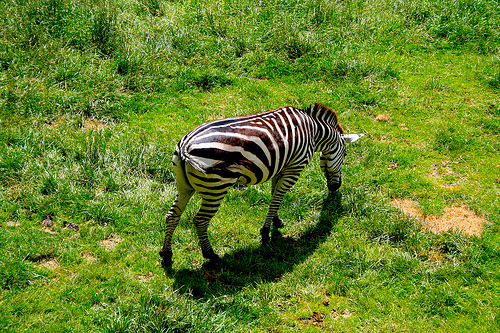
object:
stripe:
[180, 134, 272, 166]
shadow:
[168, 189, 344, 305]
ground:
[0, 1, 499, 332]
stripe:
[187, 147, 262, 187]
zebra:
[155, 100, 366, 275]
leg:
[191, 187, 223, 258]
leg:
[256, 171, 304, 232]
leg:
[158, 186, 192, 255]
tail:
[173, 144, 256, 183]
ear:
[340, 131, 367, 145]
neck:
[307, 110, 340, 153]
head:
[318, 133, 363, 195]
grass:
[0, 0, 498, 332]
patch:
[381, 195, 493, 241]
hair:
[305, 102, 349, 137]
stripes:
[220, 125, 279, 185]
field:
[0, 0, 498, 332]